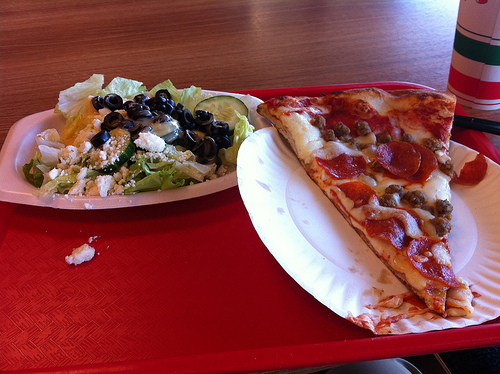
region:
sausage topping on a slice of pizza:
[427, 217, 452, 232]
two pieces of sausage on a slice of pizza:
[428, 200, 458, 239]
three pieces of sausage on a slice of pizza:
[405, 189, 450, 240]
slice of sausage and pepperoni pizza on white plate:
[240, 76, 499, 331]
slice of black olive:
[101, 94, 126, 109]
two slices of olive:
[88, 91, 126, 108]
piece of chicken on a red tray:
[63, 237, 99, 267]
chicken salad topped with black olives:
[6, 68, 270, 213]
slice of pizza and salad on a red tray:
[8, 65, 498, 372]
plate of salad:
[4, 69, 272, 210]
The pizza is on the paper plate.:
[255, 45, 499, 342]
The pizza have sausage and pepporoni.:
[358, 96, 427, 231]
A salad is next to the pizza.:
[19, 79, 216, 195]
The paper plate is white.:
[228, 144, 349, 314]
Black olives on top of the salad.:
[113, 91, 228, 159]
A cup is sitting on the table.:
[436, 6, 496, 116]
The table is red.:
[36, 219, 271, 346]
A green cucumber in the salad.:
[193, 90, 250, 140]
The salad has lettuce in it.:
[53, 80, 139, 120]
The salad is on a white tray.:
[11, 95, 222, 215]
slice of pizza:
[268, 47, 470, 309]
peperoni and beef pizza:
[282, 57, 482, 330]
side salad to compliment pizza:
[22, 51, 238, 218]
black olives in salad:
[94, 68, 245, 159]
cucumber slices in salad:
[187, 82, 254, 131]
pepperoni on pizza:
[369, 132, 435, 177]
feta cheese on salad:
[47, 166, 164, 191]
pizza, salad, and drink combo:
[17, 38, 497, 326]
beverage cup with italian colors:
[436, 9, 498, 122]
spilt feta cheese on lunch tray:
[43, 217, 155, 294]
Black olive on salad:
[90, 129, 113, 144]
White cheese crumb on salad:
[133, 127, 168, 152]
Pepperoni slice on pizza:
[313, 147, 368, 178]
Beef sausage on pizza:
[355, 115, 370, 135]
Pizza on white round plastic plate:
[252, 84, 477, 317]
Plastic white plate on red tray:
[232, 122, 497, 332]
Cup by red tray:
[446, 0, 498, 116]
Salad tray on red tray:
[0, 90, 269, 210]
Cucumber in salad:
[195, 94, 250, 131]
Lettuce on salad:
[53, 72, 106, 117]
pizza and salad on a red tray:
[5, 75, 476, 341]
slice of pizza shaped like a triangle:
[256, 76, 481, 314]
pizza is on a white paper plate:
[242, 83, 489, 309]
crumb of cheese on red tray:
[52, 231, 132, 283]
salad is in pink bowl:
[13, 58, 239, 201]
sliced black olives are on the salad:
[90, 78, 228, 153]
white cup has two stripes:
[435, 0, 496, 108]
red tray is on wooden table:
[167, 10, 407, 77]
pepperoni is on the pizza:
[330, 120, 440, 190]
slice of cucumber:
[193, 82, 248, 132]